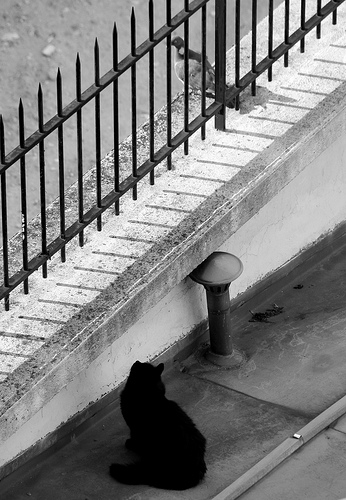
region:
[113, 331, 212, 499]
a black cat on a sidewalk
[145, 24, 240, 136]
a bird on a ledge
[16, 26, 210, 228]
a black iron fence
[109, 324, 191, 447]
a black cat looking up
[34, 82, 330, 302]
a concrete ledge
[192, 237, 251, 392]
a vent pipe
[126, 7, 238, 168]
a pigeon on a ledge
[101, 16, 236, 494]
a black cat looking at a bird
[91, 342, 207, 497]
a black cat with a tail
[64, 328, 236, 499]
a black cat next to a ledge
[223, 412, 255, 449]
part of a floor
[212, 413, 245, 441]
part of a floor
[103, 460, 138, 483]
part of a tail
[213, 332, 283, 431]
part of a floor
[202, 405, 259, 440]
part of a floor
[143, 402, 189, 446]
part of a back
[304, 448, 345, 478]
part of a road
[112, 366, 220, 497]
the cat is black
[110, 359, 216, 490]
the cat is looking up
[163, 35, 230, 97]
the dove is on the rock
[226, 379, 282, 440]
the ground is concrete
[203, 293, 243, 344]
pipe is grey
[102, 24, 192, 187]
the bars are black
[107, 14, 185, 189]
the bars are sharp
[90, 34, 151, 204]
the bars are mettallic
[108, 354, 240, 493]
the cat is looking at the dove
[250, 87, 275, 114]
the shaow is of a dove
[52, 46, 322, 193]
black wrought iron fence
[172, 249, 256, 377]
roof top vent pipe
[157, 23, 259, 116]
pigeon sitting on ledge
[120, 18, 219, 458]
cat is watching the pigeon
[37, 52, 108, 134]
spike on the top of the fence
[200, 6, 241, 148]
black iron support bar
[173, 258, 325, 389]
roof tile with tar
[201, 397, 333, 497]
edge detail on roof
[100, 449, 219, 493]
cat has long tail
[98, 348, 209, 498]
cat has long fur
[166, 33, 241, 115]
pigeon is black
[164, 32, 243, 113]
pigeon is next to wrought iron fence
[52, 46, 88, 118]
wrought iron fence is pointed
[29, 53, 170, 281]
wrought iron fence is black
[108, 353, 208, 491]
cat is black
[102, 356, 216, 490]
cat is next to fence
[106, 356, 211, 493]
black cat is next to pipe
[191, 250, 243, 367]
metal pipe is on roof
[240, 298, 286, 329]
leaves are on the roof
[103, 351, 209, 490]
black cat with long fur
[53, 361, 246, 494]
a black cat staring at a bird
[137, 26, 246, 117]
a bird sitting on a ledge